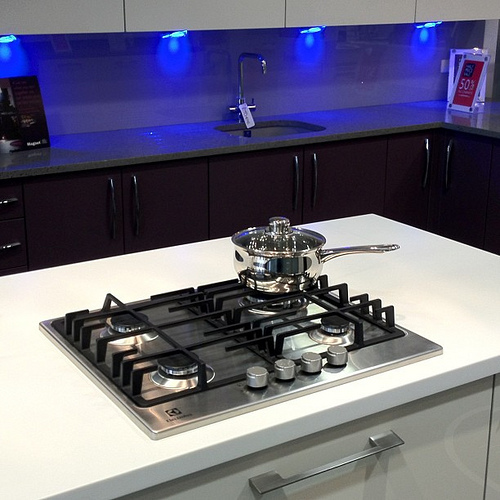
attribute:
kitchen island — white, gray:
[7, 209, 494, 499]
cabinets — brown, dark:
[0, 122, 494, 269]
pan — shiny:
[223, 209, 408, 304]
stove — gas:
[26, 262, 453, 447]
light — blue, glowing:
[150, 32, 197, 76]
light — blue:
[3, 38, 36, 78]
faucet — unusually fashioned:
[211, 43, 282, 148]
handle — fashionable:
[231, 426, 410, 499]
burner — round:
[141, 349, 214, 392]